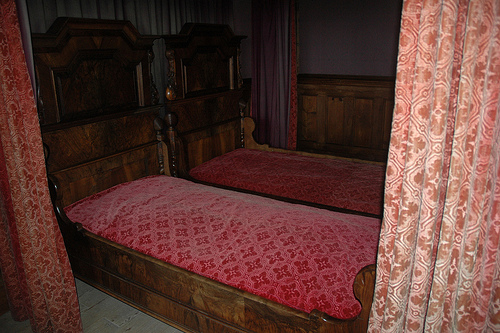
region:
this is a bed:
[127, 177, 319, 272]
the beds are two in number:
[191, 156, 344, 279]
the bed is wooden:
[111, 256, 172, 293]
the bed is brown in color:
[122, 266, 153, 293]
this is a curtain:
[407, 32, 490, 185]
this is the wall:
[307, 19, 382, 61]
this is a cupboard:
[316, 73, 384, 115]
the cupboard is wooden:
[323, 86, 380, 126]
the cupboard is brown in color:
[313, 91, 366, 124]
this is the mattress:
[159, 193, 250, 246]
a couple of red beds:
[56, 88, 421, 330]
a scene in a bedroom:
[15, 10, 492, 330]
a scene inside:
[11, 13, 484, 329]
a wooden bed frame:
[67, 211, 387, 331]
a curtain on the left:
[0, 1, 88, 328]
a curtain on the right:
[356, 2, 497, 329]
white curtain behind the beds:
[13, 5, 284, 162]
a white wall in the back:
[287, 7, 418, 82]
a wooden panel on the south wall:
[290, 64, 407, 159]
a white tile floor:
[0, 255, 210, 327]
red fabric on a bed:
[59, 173, 381, 320]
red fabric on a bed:
[192, 145, 383, 217]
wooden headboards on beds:
[22, 17, 243, 211]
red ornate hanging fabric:
[0, 0, 81, 330]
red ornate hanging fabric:
[368, 1, 498, 331]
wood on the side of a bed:
[53, 222, 374, 330]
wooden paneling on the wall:
[294, 74, 392, 159]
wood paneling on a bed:
[240, 118, 267, 150]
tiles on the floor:
[71, 276, 183, 331]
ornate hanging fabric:
[252, 4, 297, 149]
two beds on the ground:
[58, 123, 380, 289]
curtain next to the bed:
[381, 148, 498, 227]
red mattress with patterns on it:
[191, 211, 273, 273]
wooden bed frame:
[131, 267, 207, 309]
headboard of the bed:
[16, 96, 166, 205]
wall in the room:
[338, 29, 376, 51]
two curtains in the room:
[0, 20, 484, 177]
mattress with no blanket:
[114, 198, 280, 268]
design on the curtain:
[413, 131, 469, 218]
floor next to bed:
[88, 303, 118, 326]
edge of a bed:
[135, 275, 142, 293]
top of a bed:
[133, 107, 153, 145]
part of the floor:
[111, 314, 120, 319]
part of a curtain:
[411, 200, 429, 260]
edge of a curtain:
[23, 164, 41, 222]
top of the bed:
[76, 140, 89, 168]